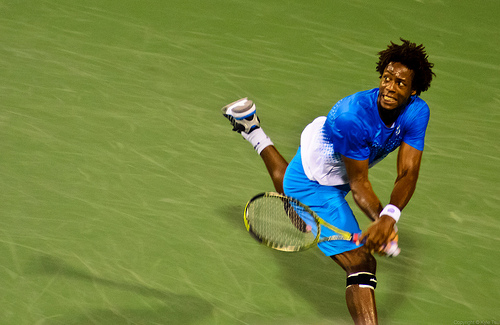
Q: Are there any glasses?
A: No, there are no glasses.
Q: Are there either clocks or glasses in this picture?
A: No, there are no glasses or clocks.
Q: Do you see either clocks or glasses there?
A: No, there are no glasses or clocks.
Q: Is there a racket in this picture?
A: Yes, there is a racket.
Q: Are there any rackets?
A: Yes, there is a racket.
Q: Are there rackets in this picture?
A: Yes, there is a racket.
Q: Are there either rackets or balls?
A: Yes, there is a racket.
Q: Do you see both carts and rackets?
A: No, there is a racket but no carts.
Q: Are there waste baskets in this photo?
A: No, there are no waste baskets.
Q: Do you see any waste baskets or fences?
A: No, there are no waste baskets or fences.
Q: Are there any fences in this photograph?
A: No, there are no fences.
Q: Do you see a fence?
A: No, there are no fences.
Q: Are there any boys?
A: No, there are no boys.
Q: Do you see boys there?
A: No, there are no boys.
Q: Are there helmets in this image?
A: No, there are no helmets.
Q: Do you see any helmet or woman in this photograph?
A: No, there are no helmets or women.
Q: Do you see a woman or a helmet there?
A: No, there are no helmets or women.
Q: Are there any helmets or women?
A: No, there are no helmets or women.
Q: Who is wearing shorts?
A: The man is wearing shorts.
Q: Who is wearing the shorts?
A: The man is wearing shorts.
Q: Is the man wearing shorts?
A: Yes, the man is wearing shorts.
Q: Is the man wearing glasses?
A: No, the man is wearing shorts.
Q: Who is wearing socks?
A: The man is wearing socks.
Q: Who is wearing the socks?
A: The man is wearing socks.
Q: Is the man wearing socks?
A: Yes, the man is wearing socks.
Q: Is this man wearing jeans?
A: No, the man is wearing socks.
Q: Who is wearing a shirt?
A: The man is wearing a shirt.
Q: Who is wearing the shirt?
A: The man is wearing a shirt.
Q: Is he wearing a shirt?
A: Yes, the man is wearing a shirt.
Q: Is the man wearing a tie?
A: No, the man is wearing a shirt.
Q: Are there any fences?
A: No, there are no fences.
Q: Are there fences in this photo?
A: No, there are no fences.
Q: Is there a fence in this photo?
A: No, there are no fences.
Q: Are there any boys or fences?
A: No, there are no fences or boys.